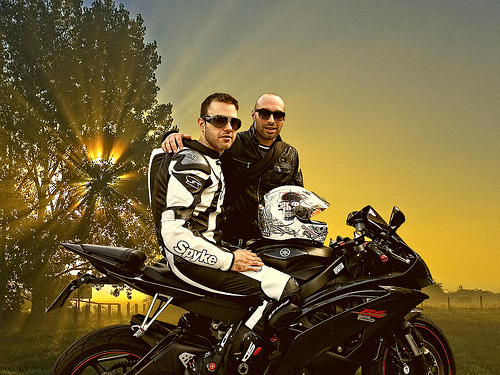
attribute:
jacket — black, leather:
[158, 143, 228, 265]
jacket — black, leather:
[224, 132, 301, 237]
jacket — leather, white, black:
[146, 138, 235, 272]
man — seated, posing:
[146, 92, 301, 373]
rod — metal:
[446, 296, 453, 309]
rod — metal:
[474, 293, 485, 310]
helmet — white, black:
[258, 183, 330, 244]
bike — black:
[49, 190, 458, 374]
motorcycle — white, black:
[77, 244, 426, 350]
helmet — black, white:
[241, 165, 358, 268]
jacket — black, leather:
[220, 133, 320, 243]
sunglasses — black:
[202, 113, 241, 129]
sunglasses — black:
[253, 108, 284, 120]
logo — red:
[349, 304, 386, 325]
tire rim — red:
[376, 316, 453, 373]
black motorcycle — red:
[44, 204, 458, 372]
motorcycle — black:
[42, 204, 456, 372]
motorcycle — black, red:
[11, 180, 488, 372]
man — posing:
[218, 91, 305, 250]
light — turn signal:
[386, 204, 405, 233]